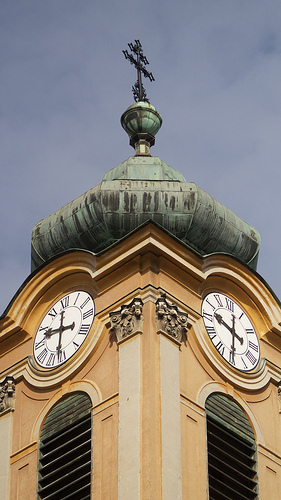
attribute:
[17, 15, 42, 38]
clouds — white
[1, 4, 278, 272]
sky — blue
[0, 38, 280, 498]
clock tower — historical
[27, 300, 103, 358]
face — white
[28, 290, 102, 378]
clock — round 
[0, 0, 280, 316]
clouds — white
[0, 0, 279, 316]
sky — blue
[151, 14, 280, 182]
sky — blue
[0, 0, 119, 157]
sky — blue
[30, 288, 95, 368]
clock — black, white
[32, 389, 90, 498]
window — velour 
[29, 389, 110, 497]
window — velour 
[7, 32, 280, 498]
building — tall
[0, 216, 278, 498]
clock tower — beige 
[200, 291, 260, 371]
clock — white, black